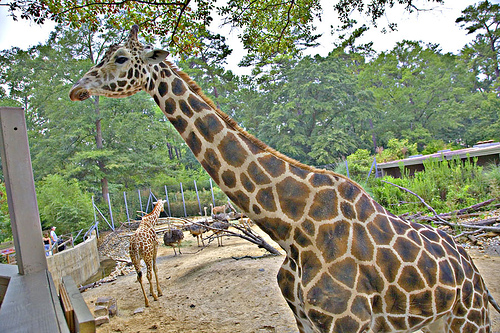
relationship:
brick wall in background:
[41, 227, 99, 298] [9, 146, 199, 283]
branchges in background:
[368, 169, 498, 206] [335, 151, 496, 221]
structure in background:
[372, 140, 494, 177] [331, 119, 498, 199]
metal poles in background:
[89, 173, 224, 230] [42, 174, 342, 242]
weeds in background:
[384, 170, 480, 215] [3, 1, 484, 240]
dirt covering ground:
[14, 219, 496, 331] [90, 216, 483, 330]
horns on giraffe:
[123, 22, 139, 42] [68, 17, 498, 331]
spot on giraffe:
[313, 217, 350, 262] [68, 17, 498, 331]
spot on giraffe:
[351, 222, 376, 260] [68, 17, 498, 331]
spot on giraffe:
[383, 282, 408, 314] [68, 17, 498, 331]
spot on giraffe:
[216, 130, 248, 167] [68, 17, 498, 331]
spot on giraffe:
[419, 232, 446, 259] [68, 17, 498, 331]